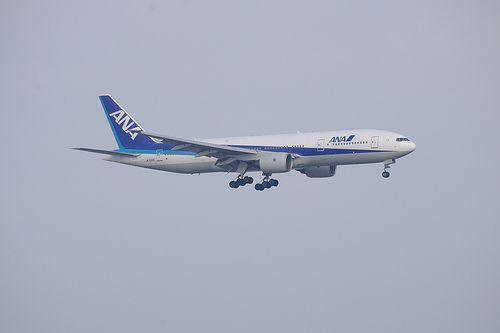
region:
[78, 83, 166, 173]
"Ana" on the plane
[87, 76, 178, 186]
The words are on the tale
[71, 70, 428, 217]
The plane is blue and white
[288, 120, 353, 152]
"Ana" is on the front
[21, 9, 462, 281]
It is sunny outside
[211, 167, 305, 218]
Wheels are coming from the bottom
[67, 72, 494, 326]
The plane is landing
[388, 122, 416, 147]
Windows on the plane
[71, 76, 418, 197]
blue and and white on the plane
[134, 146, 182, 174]
There are words on this part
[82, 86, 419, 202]
The plane is white and blue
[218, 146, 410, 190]
The landing gear is down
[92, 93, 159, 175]
The letters say ANA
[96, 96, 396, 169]
Dark blue and light blue stripe down the side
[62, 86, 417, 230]
The plane is flying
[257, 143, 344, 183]
The plane has two engines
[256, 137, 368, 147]
There are many small windows down its side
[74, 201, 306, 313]
The sky is hazy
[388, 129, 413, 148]
The front of the plane has a row of black windows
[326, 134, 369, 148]
The letters are in blue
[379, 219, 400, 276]
the sky is cloudy and dark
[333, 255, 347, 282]
the sky is cloudy and dark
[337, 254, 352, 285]
the sky is cloudy and dark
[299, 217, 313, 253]
the sky is cloudy and dark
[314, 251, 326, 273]
the sky is cloudy and dark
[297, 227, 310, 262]
the sky is cloudy and dark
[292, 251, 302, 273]
the sky is cloudy and dark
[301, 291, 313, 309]
the sky is cloudy and dark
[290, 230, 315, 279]
the sky is cloudy and blue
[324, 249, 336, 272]
the sky is cloudy and blue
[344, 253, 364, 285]
the sky is cloudy and blue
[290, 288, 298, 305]
the sky is cloudy and blue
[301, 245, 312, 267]
the sky is cloudy and blue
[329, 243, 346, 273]
the sky is cloudy and blue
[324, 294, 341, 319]
the sky is cloudy and blue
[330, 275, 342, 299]
the sky is cloudy and blue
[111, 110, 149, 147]
ana logo on plane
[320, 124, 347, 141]
ana logo on plane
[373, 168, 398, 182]
front landing wheels on plane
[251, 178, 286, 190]
landing wheels on plane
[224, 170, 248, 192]
landing wheels on plane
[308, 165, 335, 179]
engine on side of plane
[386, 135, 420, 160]
nose on front of plane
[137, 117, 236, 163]
wing on side of plane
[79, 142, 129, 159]
wing on back of plane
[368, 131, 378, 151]
door on side of plane